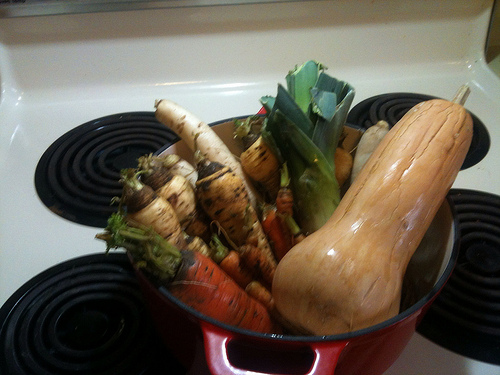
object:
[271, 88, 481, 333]
squash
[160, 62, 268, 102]
reflection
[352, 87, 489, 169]
burner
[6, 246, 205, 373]
burner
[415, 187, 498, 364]
burner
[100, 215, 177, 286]
top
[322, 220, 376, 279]
shine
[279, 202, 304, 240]
veggies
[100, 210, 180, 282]
veggies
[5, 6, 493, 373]
oven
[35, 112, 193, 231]
burner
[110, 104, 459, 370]
bowl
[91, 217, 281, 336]
carrot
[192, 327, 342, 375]
handle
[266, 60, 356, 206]
leaves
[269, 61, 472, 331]
vegetable